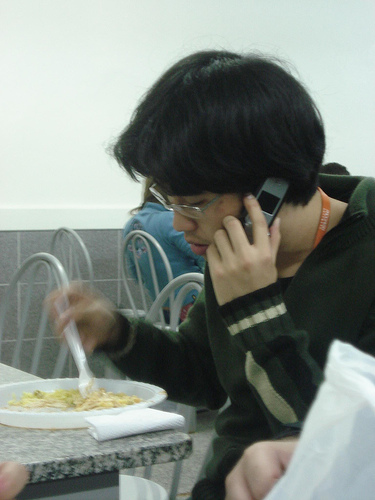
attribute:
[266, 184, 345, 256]
neck — boy's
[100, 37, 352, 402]
man — young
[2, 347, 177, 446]
bowl — white, silver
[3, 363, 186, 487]
table — granite, stone, grey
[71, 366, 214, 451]
napkin — white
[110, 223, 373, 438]
sweatshirt — long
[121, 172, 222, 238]
glasses — silver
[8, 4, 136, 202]
wall — white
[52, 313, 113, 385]
spoon — silver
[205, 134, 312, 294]
phone — black, grey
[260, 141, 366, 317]
neck — orange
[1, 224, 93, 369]
chair — gray, grey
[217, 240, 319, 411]
sweater — white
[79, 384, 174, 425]
tissue — white